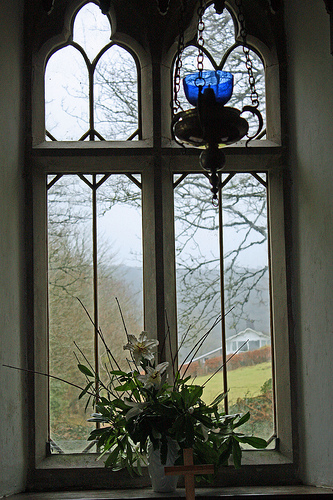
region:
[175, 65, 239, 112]
candle surrounded by blue glass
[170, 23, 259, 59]
three chains hanging from ceiling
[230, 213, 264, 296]
branches with no leaves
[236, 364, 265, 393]
grss on a hill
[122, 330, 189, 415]
two white flowers and green leaves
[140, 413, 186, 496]
green leaves over white vase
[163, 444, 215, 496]
wood cross in front of window sill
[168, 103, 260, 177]
decorative hanging candle holder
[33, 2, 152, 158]
decorative shaped window top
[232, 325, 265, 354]
white house with windows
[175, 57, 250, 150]
a blue lamp on top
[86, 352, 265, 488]
a green leaf near window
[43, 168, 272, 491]
a small window to wall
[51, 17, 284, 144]
top parts of the window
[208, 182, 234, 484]
a small thin iron rod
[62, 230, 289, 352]
a beautiful view of clouds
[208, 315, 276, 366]
a beautiful white building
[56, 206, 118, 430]
a beautiful green trees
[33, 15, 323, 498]
a big long windows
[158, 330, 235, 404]
few parts of the tree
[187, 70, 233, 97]
The candle holder is blue.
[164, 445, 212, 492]
The cross is brown wood.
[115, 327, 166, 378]
The lily's are yellow and white.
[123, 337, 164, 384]
There are white lily's in the vase.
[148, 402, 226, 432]
There are green leaves in the vase.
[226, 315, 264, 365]
A house is in the background.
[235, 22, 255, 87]
Chains are holding the candle holder.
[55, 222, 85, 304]
Bare trees are in the background.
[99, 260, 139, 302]
There are mountains in the background.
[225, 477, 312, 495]
The ledge is cement.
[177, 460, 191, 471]
a cross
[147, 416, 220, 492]
a cross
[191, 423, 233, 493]
a cross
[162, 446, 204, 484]
a cross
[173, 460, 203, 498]
a cross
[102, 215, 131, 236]
this is the sky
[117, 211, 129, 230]
the sky is blue in color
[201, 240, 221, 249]
the sky is cloudy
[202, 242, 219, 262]
the clouds are white in color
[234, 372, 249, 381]
this is the grass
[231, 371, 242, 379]
the grass is green in color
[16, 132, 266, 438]
this is a window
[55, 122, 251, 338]
the window is closed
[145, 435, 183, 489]
this is a vase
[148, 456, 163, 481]
the vase is white in color